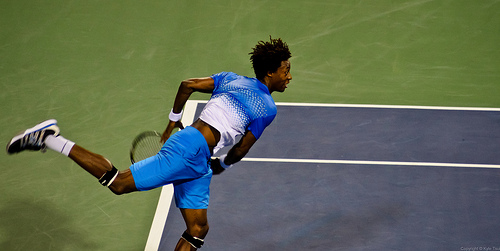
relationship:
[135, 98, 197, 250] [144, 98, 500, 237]
line on tennis court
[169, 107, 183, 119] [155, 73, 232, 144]
wristband on arm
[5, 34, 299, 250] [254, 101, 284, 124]
tennis player has shoulder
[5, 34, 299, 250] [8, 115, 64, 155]
tennis player wearing shoe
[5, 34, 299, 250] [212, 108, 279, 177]
tennis player has arm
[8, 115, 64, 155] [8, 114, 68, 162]
shoe on foot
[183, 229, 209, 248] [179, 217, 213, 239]
band on knee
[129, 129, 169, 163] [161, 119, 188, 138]
racket in hand